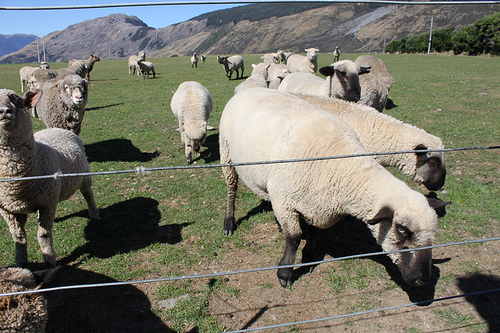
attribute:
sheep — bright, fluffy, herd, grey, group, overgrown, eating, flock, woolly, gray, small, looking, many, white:
[251, 108, 442, 238]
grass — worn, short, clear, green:
[160, 174, 188, 191]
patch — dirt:
[193, 264, 247, 292]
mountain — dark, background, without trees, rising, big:
[53, 8, 140, 61]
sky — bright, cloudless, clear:
[166, 10, 184, 17]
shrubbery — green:
[397, 41, 417, 51]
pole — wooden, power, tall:
[424, 15, 439, 51]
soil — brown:
[298, 300, 319, 313]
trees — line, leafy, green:
[378, 18, 483, 51]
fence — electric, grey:
[113, 152, 172, 174]